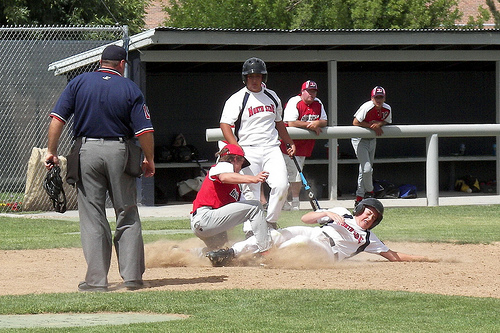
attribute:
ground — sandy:
[0, 189, 499, 331]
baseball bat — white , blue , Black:
[281, 139, 317, 217]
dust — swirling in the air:
[129, 238, 349, 278]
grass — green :
[272, 293, 439, 331]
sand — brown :
[366, 248, 487, 316]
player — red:
[181, 137, 287, 279]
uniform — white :
[187, 136, 266, 258]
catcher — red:
[187, 142, 290, 270]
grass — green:
[1, 203, 498, 331]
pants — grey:
[65, 132, 155, 283]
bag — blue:
[390, 183, 418, 200]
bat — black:
[282, 141, 333, 234]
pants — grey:
[191, 200, 272, 250]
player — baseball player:
[210, 196, 435, 265]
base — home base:
[266, 254, 316, 267]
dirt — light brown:
[1, 235, 498, 331]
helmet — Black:
[242, 55, 268, 97]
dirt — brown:
[2, 247, 494, 287]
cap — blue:
[91, 41, 135, 68]